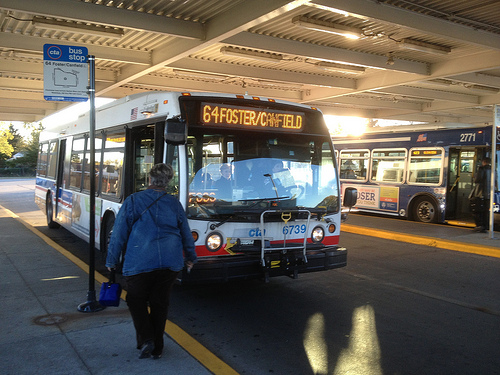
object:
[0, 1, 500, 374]
photo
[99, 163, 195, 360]
woman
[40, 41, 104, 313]
busstop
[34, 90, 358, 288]
bus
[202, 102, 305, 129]
foster/canfield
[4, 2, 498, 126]
roof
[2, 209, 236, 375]
sidewalk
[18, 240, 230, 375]
curb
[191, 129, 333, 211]
widshield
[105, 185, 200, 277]
coat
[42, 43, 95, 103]
sign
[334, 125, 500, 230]
bus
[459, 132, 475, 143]
numbers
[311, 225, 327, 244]
headlights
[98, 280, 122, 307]
bag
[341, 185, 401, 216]
advertisement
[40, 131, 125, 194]
windows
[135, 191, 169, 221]
strap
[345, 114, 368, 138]
sun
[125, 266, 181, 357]
pants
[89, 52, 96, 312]
pole